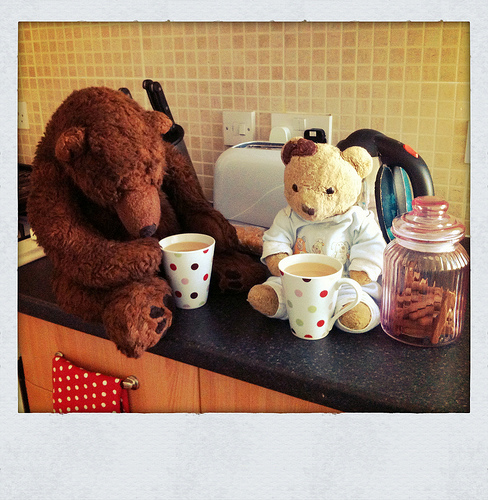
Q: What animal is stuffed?
A: Bear.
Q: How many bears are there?
A: 2.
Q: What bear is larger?
A: Left bear.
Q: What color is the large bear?
A: Dark brown.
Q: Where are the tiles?
A: Wall.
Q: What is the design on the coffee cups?
A: Polka dots.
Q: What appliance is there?
A: Toaster.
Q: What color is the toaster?
A: White.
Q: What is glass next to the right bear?
A: Cookie jar.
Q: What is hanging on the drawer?
A: Towel.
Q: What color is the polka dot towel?
A: Red.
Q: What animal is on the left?
A: A bear.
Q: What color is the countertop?
A: Black.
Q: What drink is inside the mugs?
A: Coffee.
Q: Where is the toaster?
A: Behind the animals.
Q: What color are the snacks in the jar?
A: Brown.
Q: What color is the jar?
A: Clear.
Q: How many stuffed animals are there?
A: 2.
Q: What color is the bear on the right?
A: Tan.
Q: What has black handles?
A: Set of knives.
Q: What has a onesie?
A: Teddy bear.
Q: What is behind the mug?
A: Stuffed animal.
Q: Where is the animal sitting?
A: Behind a mug.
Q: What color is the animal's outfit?
A: White.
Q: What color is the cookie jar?
A: Pink.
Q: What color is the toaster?
A: White.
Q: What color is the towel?
A: Red and white.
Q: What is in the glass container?
A: Food.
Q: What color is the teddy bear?
A: Light brown.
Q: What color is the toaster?
A: White.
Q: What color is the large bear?
A: Dark brown.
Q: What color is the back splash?
A: Tan.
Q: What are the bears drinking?
A: Coffee.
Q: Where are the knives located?
A: Behind the brown bear.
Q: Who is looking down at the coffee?
A: The bears.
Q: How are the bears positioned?
A: Sitting.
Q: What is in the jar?
A: Biscotti.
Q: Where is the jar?
A: Beside the bear.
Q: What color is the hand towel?
A: Red and white.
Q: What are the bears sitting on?
A: The countertop.